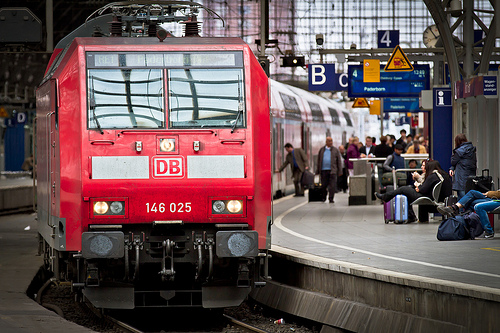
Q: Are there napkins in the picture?
A: No, there are no napkins.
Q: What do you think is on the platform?
A: The luggage is on the platform.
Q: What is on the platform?
A: The luggage is on the platform.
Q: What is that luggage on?
A: The luggage is on the platform.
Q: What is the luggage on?
A: The luggage is on the platform.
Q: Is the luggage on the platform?
A: Yes, the luggage is on the platform.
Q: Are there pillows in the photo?
A: No, there are no pillows.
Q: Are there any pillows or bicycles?
A: No, there are no pillows or bicycles.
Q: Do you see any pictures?
A: No, there are no pictures.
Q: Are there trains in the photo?
A: Yes, there is a train.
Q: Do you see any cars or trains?
A: Yes, there is a train.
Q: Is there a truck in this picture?
A: No, there are no trucks.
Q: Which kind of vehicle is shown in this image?
A: The vehicle is a train.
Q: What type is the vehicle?
A: The vehicle is a train.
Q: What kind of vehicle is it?
A: The vehicle is a train.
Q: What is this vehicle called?
A: That is a train.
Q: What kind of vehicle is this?
A: That is a train.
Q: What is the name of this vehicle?
A: That is a train.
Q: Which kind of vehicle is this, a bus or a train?
A: That is a train.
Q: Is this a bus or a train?
A: This is a train.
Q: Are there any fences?
A: No, there are no fences.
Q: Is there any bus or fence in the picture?
A: No, there are no fences or buses.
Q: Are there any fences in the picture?
A: No, there are no fences.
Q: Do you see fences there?
A: No, there are no fences.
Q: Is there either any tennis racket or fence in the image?
A: No, there are no fences or rackets.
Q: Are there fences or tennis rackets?
A: No, there are no fences or tennis rackets.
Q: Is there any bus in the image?
A: No, there are no buses.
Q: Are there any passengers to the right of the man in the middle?
A: Yes, there is a passenger to the right of the man.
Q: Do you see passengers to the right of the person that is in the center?
A: Yes, there is a passenger to the right of the man.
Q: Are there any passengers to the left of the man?
A: No, the passenger is to the right of the man.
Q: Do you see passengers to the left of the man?
A: No, the passenger is to the right of the man.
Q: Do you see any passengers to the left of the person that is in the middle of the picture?
A: No, the passenger is to the right of the man.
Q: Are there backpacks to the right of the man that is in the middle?
A: No, there is a passenger to the right of the man.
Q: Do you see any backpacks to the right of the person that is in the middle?
A: No, there is a passenger to the right of the man.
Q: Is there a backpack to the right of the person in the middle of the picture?
A: No, there is a passenger to the right of the man.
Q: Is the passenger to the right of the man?
A: Yes, the passenger is to the right of the man.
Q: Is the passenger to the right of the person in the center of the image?
A: Yes, the passenger is to the right of the man.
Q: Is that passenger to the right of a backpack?
A: No, the passenger is to the right of the man.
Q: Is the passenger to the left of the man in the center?
A: No, the passenger is to the right of the man.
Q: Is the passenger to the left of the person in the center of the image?
A: No, the passenger is to the right of the man.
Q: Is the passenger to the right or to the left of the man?
A: The passenger is to the right of the man.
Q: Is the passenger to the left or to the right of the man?
A: The passenger is to the right of the man.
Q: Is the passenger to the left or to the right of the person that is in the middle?
A: The passenger is to the right of the man.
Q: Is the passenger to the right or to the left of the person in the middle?
A: The passenger is to the right of the man.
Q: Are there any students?
A: No, there are no students.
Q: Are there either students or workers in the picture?
A: No, there are no students or workers.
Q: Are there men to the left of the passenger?
A: Yes, there is a man to the left of the passenger.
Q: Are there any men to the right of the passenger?
A: No, the man is to the left of the passenger.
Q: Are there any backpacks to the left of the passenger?
A: No, there is a man to the left of the passenger.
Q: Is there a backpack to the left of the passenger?
A: No, there is a man to the left of the passenger.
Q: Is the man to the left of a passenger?
A: Yes, the man is to the left of a passenger.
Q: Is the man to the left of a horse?
A: No, the man is to the left of a passenger.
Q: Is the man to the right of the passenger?
A: No, the man is to the left of the passenger.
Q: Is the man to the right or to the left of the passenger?
A: The man is to the left of the passenger.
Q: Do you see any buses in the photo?
A: No, there are no buses.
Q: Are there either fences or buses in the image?
A: No, there are no buses or fences.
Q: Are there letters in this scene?
A: Yes, there are letters.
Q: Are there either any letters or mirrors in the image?
A: Yes, there are letters.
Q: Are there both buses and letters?
A: No, there are letters but no buses.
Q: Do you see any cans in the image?
A: No, there are no cans.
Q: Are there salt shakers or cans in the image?
A: No, there are no cans or salt shakers.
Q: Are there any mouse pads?
A: No, there are no mouse pads.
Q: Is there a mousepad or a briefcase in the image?
A: No, there are no mouse pads or briefcases.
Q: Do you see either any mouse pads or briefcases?
A: No, there are no mouse pads or briefcases.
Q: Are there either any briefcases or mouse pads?
A: No, there are no mouse pads or briefcases.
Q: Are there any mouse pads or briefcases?
A: No, there are no mouse pads or briefcases.